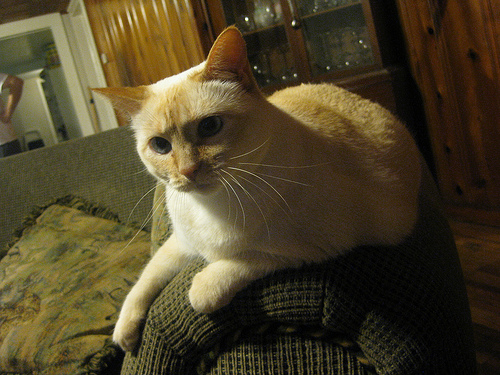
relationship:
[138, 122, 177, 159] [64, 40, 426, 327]
eye of cat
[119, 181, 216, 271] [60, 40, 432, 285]
whiskers of cat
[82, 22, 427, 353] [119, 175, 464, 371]
cat on sofa arm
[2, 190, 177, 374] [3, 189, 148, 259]
pillow with fringe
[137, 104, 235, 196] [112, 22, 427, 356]
face of cat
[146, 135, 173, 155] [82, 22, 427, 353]
eye of cat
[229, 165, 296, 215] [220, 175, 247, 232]
whisker of whisker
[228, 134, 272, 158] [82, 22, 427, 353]
whisker of cat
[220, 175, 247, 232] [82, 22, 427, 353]
whisker of cat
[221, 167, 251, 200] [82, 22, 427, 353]
whisker of cat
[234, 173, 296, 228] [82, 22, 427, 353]
whisker of cat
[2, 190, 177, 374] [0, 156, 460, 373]
pillow on couch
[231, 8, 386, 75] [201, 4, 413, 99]
window on cabinet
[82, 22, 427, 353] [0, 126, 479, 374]
cat on couch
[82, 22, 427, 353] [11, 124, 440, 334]
cat on couch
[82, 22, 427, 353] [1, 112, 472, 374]
cat sitting couch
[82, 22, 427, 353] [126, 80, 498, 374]
cat sitting on couch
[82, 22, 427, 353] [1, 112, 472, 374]
cat sitting on couch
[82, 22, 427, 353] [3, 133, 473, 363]
cat sitting on couch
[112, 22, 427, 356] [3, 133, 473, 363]
cat sitting on couch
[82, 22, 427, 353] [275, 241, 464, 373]
cat sitting on couch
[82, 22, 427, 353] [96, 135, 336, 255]
cat with whiskers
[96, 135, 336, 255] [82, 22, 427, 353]
whiskers on cat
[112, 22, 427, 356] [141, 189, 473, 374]
cat on sofa arm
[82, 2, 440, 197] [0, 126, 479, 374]
cabinet next to couch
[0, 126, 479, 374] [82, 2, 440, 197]
couch next to cabinet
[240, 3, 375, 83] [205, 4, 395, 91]
cups in cabinet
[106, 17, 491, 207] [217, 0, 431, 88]
wall by cabinet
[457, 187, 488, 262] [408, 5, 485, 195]
floor by wall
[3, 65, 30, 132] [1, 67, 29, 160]
arm/elbow on persoin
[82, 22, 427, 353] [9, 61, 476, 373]
cat on sofa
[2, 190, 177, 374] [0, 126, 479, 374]
pillow on couch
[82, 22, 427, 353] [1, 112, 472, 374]
cat is on couch